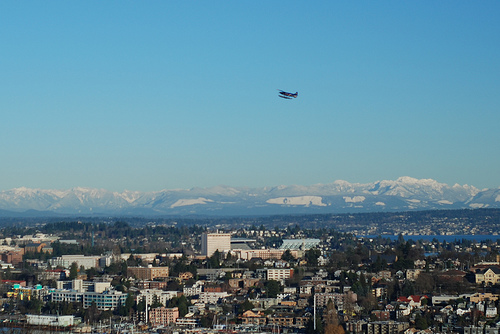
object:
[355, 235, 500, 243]
water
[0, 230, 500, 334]
city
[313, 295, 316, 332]
pole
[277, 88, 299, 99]
airplane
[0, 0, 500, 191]
sky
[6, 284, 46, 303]
building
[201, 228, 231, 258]
building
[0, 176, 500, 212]
snow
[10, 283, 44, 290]
mounds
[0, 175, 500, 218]
mountains